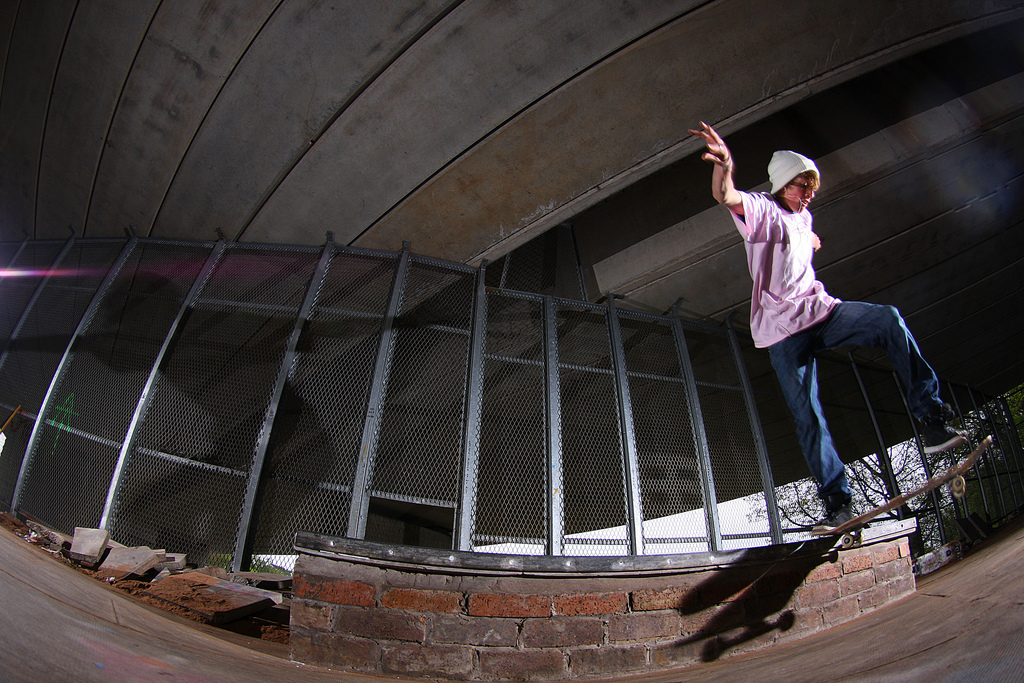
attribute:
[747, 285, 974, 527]
jeans — dark blue denim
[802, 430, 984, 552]
skateboard — wood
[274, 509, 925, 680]
brick — small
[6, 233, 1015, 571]
fence — large, silver, metal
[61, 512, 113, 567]
piece — concrete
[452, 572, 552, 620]
brick — red, old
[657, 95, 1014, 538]
people — outdoor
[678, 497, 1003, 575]
skateboard — large, in air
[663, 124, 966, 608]
man — wearing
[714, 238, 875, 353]
shirt — pink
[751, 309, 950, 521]
jeans — blue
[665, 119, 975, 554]
man — wearing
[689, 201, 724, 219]
arm — raised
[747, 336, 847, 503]
leg — bent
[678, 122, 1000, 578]
man — wearing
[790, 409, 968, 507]
shoes — black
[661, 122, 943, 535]
person — wearing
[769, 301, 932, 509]
pants — black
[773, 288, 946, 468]
pants — blue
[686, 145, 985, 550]
person — wearing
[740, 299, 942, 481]
pants — blue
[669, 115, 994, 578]
person — wearing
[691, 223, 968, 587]
person — wearing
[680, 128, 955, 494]
person — wearing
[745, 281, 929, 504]
jeans — blue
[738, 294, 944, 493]
jeans — blue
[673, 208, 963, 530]
person — wearing